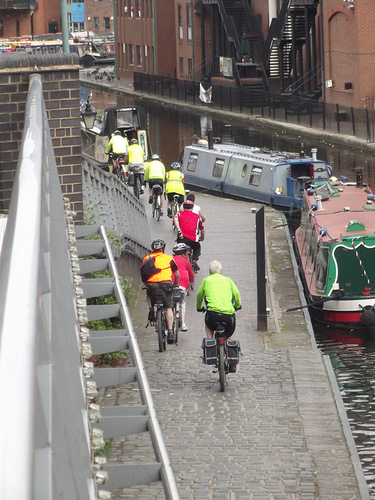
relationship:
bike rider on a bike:
[141, 238, 180, 345] [135, 283, 181, 352]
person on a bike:
[171, 242, 193, 331] [170, 289, 182, 327]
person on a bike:
[164, 161, 183, 217] [169, 193, 179, 228]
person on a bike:
[107, 131, 125, 170] [102, 151, 128, 181]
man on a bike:
[123, 143, 147, 195] [125, 161, 142, 201]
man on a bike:
[141, 154, 166, 216] [144, 177, 162, 217]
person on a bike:
[168, 158, 183, 205] [163, 191, 178, 219]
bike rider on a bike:
[197, 258, 241, 373] [203, 325, 238, 390]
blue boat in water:
[179, 139, 338, 218] [315, 334, 373, 440]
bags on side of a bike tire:
[200, 337, 245, 374] [214, 335, 230, 394]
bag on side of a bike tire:
[202, 336, 216, 363] [214, 335, 230, 394]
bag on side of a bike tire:
[225, 338, 239, 372] [214, 335, 230, 394]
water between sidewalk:
[115, 98, 191, 151] [75, 63, 374, 148]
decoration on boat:
[351, 237, 371, 288] [277, 178, 372, 318]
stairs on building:
[282, 82, 321, 117] [113, 2, 373, 127]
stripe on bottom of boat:
[315, 310, 363, 321] [290, 167, 373, 335]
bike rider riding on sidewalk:
[197, 258, 241, 390] [95, 172, 370, 498]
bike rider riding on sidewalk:
[141, 238, 180, 345] [95, 172, 370, 498]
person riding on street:
[171, 242, 195, 331] [137, 177, 361, 495]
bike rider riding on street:
[197, 258, 241, 373] [190, 183, 270, 373]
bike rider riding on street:
[141, 238, 180, 345] [190, 183, 270, 373]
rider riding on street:
[176, 195, 202, 253] [190, 183, 270, 373]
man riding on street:
[123, 143, 147, 195] [190, 183, 270, 373]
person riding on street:
[166, 160, 186, 220] [190, 183, 270, 373]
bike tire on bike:
[218, 342, 225, 392] [196, 301, 242, 392]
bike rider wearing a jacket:
[197, 258, 241, 373] [200, 268, 238, 317]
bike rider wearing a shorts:
[197, 258, 241, 373] [203, 309, 235, 338]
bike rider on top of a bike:
[197, 258, 241, 373] [197, 307, 238, 390]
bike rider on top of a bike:
[141, 238, 180, 345] [142, 288, 172, 352]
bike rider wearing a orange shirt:
[141, 238, 180, 345] [138, 247, 179, 285]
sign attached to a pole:
[68, 3, 84, 24] [58, 4, 68, 54]